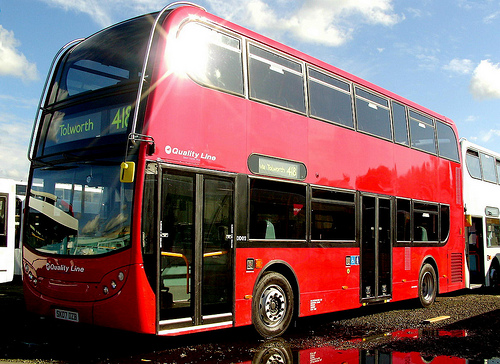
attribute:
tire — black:
[247, 273, 305, 344]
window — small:
[349, 80, 394, 143]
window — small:
[178, 23, 473, 168]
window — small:
[434, 117, 461, 162]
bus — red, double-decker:
[19, 0, 465, 338]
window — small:
[248, 176, 305, 238]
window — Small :
[241, 177, 312, 248]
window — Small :
[57, 41, 142, 99]